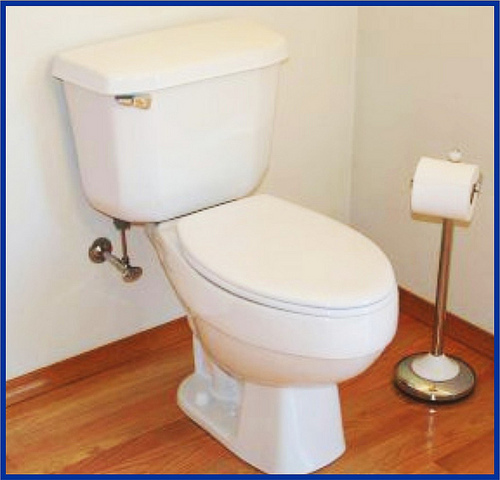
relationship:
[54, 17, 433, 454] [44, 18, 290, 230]
toilet has tank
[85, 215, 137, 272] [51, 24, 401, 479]
pipes in toilet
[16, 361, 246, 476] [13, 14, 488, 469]
hardwood floor in bathroom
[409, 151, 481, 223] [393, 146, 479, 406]
toilet paper on stand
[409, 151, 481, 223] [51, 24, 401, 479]
toilet paper besides toilet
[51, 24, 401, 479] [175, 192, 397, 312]
toilet has lid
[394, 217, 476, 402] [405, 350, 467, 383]
paper holder has base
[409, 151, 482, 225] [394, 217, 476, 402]
toilet paper on paper holder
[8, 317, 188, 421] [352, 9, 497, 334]
baseboard on wall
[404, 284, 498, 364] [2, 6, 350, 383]
baseboard on wall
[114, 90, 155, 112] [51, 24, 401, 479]
handle on toilet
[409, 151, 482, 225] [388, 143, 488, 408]
toilet paper on holder